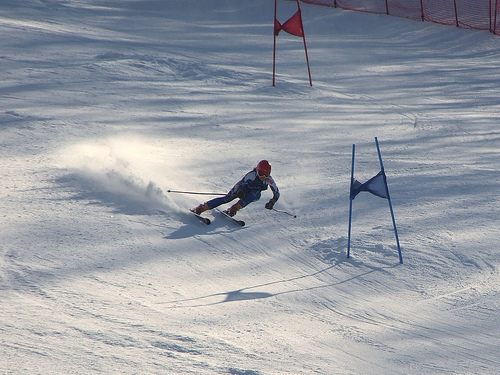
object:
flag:
[344, 135, 406, 266]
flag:
[268, 0, 317, 86]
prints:
[246, 264, 500, 374]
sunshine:
[3, 263, 344, 373]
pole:
[270, 0, 279, 86]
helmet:
[255, 158, 273, 178]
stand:
[344, 134, 406, 272]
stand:
[268, 1, 318, 90]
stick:
[372, 136, 405, 263]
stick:
[342, 144, 357, 257]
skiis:
[182, 205, 213, 227]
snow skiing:
[166, 159, 300, 228]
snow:
[0, 0, 500, 374]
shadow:
[157, 256, 385, 310]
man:
[189, 159, 281, 223]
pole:
[159, 185, 232, 200]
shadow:
[164, 210, 249, 241]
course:
[160, 158, 301, 228]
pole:
[372, 134, 407, 266]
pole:
[346, 142, 361, 257]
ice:
[1, 0, 500, 374]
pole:
[265, 201, 302, 219]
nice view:
[0, 0, 500, 374]